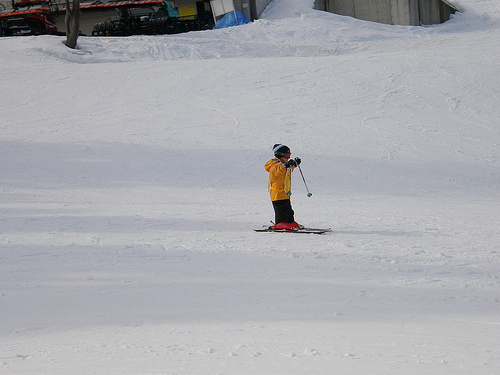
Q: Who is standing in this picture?
A: A boy.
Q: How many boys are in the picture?
A: One.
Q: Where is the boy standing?
A: AT a snow covered field.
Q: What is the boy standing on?
A: Skis.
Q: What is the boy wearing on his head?
A: A hat.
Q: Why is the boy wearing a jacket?
A: Because it is cold outside.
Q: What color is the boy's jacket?
A: Yellow.